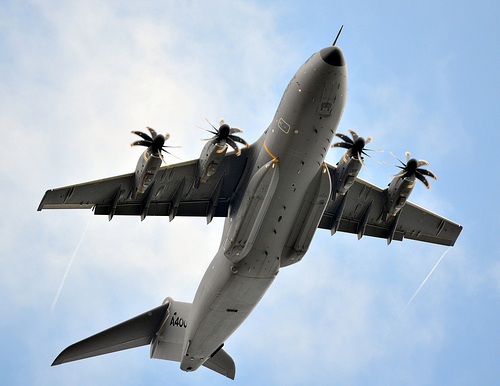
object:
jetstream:
[401, 241, 455, 317]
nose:
[317, 47, 345, 71]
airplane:
[32, 27, 464, 382]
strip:
[255, 136, 279, 171]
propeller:
[330, 124, 378, 174]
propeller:
[388, 148, 438, 188]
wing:
[44, 138, 243, 228]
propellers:
[123, 114, 438, 192]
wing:
[319, 162, 463, 251]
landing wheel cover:
[214, 264, 271, 317]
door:
[271, 114, 290, 138]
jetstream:
[45, 205, 115, 312]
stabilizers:
[222, 152, 335, 273]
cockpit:
[276, 47, 350, 128]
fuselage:
[165, 209, 306, 379]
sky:
[3, 4, 497, 384]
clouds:
[40, 23, 336, 293]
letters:
[165, 310, 202, 335]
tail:
[49, 292, 260, 386]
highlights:
[239, 122, 355, 181]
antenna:
[329, 22, 346, 49]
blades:
[129, 125, 174, 154]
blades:
[205, 118, 241, 148]